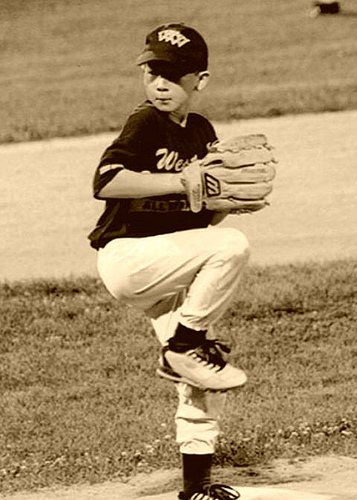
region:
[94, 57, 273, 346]
A kid playing baseball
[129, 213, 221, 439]
A kid playing baseball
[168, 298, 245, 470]
A kid playing baseball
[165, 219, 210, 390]
A kid playing baseball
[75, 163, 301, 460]
A kid playing baseball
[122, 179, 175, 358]
A kid playing baseball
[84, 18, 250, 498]
a boy is playing baseball.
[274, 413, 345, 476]
a brown field of dirt.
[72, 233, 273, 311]
a boy is wearing white pants.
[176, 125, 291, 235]
the boy is wearing a baseball glove.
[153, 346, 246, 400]
a boy is wearing black and white baseball sneakers.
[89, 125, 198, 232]
the baseball player is left handed.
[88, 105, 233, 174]
the baseball player is wearing a black and white shirt.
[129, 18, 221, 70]
the baseball player is wearing a black graffiti baseball cap.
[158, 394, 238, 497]
the baseball player is standing on his left leg.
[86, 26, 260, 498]
baseball player is throwing the ball.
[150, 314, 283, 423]
right cleat of kid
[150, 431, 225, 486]
black sock on kid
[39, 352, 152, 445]
grass behind the kid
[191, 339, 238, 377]
shoelaces on right cleat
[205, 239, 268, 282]
right knee on pitcher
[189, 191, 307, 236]
glove on right hand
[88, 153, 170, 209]
right elbow of pitcher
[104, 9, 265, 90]
black hat of pitcher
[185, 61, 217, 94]
left ear of pitcher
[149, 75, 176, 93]
nose of the pitcher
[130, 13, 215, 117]
baseball cap on a kid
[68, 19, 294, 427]
kids playing baseball in old fashioned outfit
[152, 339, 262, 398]
white baseball cleats with black laces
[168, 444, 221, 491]
black baseball socks on kid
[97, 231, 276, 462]
white baseball pants on kid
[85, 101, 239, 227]
baseball jersey on a kid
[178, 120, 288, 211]
kid's baseball mitt on hand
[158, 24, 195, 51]
white logo on baseball cap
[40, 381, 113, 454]
unmowed grass on a little league field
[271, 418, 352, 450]
clover growing on a field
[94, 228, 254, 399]
Boy with his leg up.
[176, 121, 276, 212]
He wears a baseball glove.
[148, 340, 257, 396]
The shoe of the boy.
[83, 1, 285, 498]
The boy get read to throw.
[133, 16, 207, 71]
The boy wears a hat.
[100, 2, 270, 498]
The pitche in a unifrom.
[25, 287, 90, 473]
Grass in the infield.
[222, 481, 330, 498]
The white pitchers mound.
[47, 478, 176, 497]
Dirt on the mound.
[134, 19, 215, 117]
Fierce look on boys face.